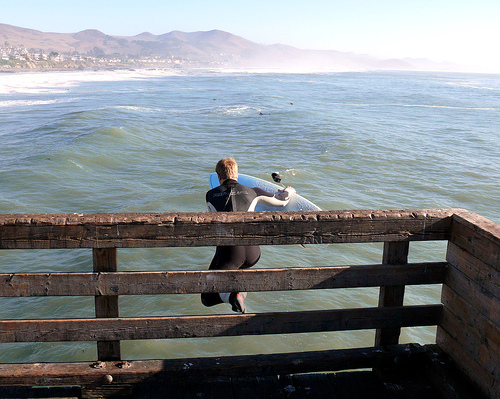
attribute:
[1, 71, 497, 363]
water — pictured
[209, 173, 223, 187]
surf board — blue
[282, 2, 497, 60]
sky — blue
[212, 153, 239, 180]
hair — cut , short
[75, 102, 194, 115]
wave — ocean wave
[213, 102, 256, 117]
wave — ocean wave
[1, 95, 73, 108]
wave — ocean wave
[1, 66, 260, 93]
wave — ocean wave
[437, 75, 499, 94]
wave — ocean wave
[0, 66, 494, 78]
beach — white, sandy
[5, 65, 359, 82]
surf — white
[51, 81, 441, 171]
ocean — greenish-gray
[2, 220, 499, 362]
railing — old, brown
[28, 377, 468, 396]
platform — elevated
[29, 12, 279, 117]
hills — brown 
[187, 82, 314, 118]
birds — black, round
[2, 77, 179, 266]
wave — small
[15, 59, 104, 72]
bank — green , brown 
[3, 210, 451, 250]
beam — brown, wooden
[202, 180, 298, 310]
wetsuit — black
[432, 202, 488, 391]
wall — solid, wood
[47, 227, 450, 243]
lines — deep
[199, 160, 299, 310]
surfer — jumping